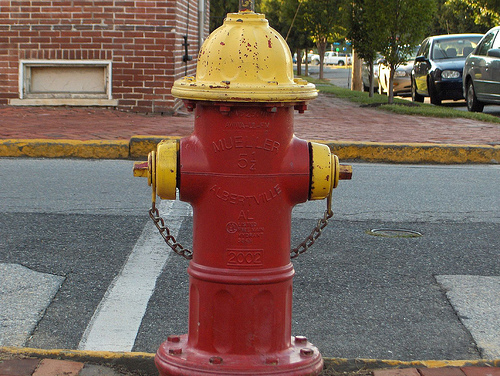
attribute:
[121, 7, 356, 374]
hydrant — MUELLER 51/2 ALBERVILLE , yellow fire , red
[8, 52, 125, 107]
casement — white basement window 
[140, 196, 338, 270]
chain —  fire hydrant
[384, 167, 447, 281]
street — concrete city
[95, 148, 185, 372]
markings — white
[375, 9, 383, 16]
leaves — green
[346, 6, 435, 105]
tree — small